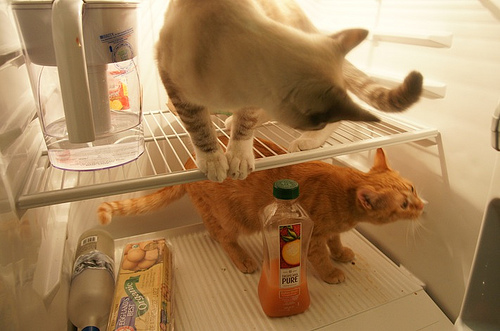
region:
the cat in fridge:
[152, 3, 426, 165]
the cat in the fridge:
[136, 173, 401, 283]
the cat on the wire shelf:
[157, 8, 405, 158]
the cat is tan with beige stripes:
[152, 9, 423, 153]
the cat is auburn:
[184, 158, 422, 295]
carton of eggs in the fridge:
[114, 235, 182, 325]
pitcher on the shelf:
[19, 8, 159, 169]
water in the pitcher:
[47, 119, 148, 160]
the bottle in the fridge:
[77, 219, 117, 329]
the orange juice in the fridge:
[247, 178, 323, 312]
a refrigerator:
[8, 5, 498, 312]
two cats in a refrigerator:
[93, 5, 460, 291]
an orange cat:
[134, 152, 433, 297]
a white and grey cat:
[142, 8, 419, 167]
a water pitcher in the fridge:
[17, 9, 149, 171]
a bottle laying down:
[75, 223, 110, 324]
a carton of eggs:
[115, 240, 178, 330]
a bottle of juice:
[266, 184, 309, 329]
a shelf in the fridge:
[19, 108, 444, 176]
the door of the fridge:
[449, 93, 499, 323]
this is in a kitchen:
[22, 11, 455, 251]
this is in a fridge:
[25, 49, 467, 308]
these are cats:
[170, 32, 455, 309]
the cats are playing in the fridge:
[118, 11, 415, 321]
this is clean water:
[15, 35, 170, 190]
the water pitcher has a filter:
[25, 93, 166, 191]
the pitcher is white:
[35, 12, 132, 75]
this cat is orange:
[197, 175, 430, 243]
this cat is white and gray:
[168, 8, 363, 153]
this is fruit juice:
[255, 229, 315, 319]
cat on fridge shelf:
[136, 13, 357, 150]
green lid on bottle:
[263, 181, 307, 213]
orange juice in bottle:
[225, 214, 317, 315]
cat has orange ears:
[361, 143, 393, 218]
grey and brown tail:
[302, 24, 417, 127]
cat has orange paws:
[227, 200, 364, 287]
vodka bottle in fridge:
[72, 219, 111, 329]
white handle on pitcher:
[20, 3, 152, 174]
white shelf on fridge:
[86, 89, 391, 196]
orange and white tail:
[97, 188, 199, 229]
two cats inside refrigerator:
[101, 0, 428, 288]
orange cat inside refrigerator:
[96, 135, 427, 282]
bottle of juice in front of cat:
[256, 176, 311, 317]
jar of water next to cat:
[9, 0, 145, 173]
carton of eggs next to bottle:
[106, 240, 176, 330]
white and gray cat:
[155, 1, 423, 181]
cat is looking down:
[153, 0, 424, 180]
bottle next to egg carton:
[69, 228, 115, 329]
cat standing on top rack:
[149, 1, 425, 183]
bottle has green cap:
[256, 178, 311, 318]